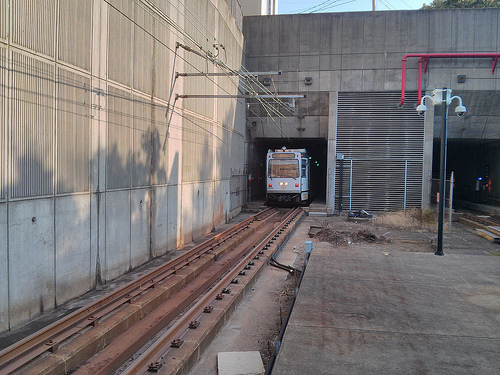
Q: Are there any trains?
A: Yes, there is a train.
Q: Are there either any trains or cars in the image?
A: Yes, there is a train.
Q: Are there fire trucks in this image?
A: No, there are no fire trucks.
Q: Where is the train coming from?
A: The train is coming from the tunnel.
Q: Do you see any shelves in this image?
A: No, there are no shelves.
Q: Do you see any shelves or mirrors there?
A: No, there are no shelves or mirrors.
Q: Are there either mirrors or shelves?
A: No, there are no shelves or mirrors.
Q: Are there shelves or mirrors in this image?
A: No, there are no shelves or mirrors.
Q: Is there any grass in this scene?
A: Yes, there is grass.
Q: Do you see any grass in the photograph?
A: Yes, there is grass.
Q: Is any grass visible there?
A: Yes, there is grass.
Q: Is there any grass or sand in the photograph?
A: Yes, there is grass.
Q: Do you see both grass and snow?
A: No, there is grass but no snow.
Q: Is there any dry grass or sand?
A: Yes, there is dry grass.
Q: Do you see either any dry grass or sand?
A: Yes, there is dry grass.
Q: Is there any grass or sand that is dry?
A: Yes, the grass is dry.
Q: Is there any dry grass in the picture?
A: Yes, there is dry grass.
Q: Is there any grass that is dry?
A: Yes, there is grass that is dry.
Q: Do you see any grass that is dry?
A: Yes, there is grass that is dry.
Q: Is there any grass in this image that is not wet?
A: Yes, there is dry grass.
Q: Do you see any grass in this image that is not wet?
A: Yes, there is dry grass.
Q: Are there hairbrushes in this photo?
A: No, there are no hairbrushes.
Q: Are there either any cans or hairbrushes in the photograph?
A: No, there are no hairbrushes or cans.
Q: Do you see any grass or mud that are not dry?
A: No, there is grass but it is dry.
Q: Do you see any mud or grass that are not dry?
A: No, there is grass but it is dry.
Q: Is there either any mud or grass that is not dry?
A: No, there is grass but it is dry.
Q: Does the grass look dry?
A: Yes, the grass is dry.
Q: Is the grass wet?
A: No, the grass is dry.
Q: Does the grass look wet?
A: No, the grass is dry.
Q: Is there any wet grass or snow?
A: No, there is grass but it is dry.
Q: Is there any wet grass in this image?
A: No, there is grass but it is dry.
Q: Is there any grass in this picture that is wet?
A: No, there is grass but it is dry.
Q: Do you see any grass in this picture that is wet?
A: No, there is grass but it is dry.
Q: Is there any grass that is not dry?
A: No, there is grass but it is dry.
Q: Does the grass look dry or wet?
A: The grass is dry.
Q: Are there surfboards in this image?
A: No, there are no surfboards.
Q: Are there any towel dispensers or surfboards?
A: No, there are no surfboards or towel dispensers.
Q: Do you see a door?
A: Yes, there is a door.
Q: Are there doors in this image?
A: Yes, there is a door.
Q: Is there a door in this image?
A: Yes, there is a door.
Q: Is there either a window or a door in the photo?
A: Yes, there is a door.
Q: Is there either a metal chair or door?
A: Yes, there is a metal door.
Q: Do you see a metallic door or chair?
A: Yes, there is a metal door.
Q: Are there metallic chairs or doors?
A: Yes, there is a metal door.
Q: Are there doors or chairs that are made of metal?
A: Yes, the door is made of metal.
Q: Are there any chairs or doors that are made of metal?
A: Yes, the door is made of metal.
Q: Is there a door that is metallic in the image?
A: Yes, there is a metal door.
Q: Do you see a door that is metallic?
A: Yes, there is a door that is metallic.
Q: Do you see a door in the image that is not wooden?
A: Yes, there is a metallic door.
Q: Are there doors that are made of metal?
A: Yes, there is a door that is made of metal.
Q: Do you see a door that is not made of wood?
A: Yes, there is a door that is made of metal.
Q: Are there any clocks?
A: No, there are no clocks.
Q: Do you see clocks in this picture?
A: No, there are no clocks.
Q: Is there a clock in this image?
A: No, there are no clocks.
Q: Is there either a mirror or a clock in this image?
A: No, there are no clocks or mirrors.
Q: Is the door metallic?
A: Yes, the door is metallic.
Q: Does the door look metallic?
A: Yes, the door is metallic.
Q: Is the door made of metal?
A: Yes, the door is made of metal.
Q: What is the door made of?
A: The door is made of metal.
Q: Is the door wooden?
A: No, the door is metallic.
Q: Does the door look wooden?
A: No, the door is metallic.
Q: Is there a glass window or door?
A: No, there is a door but it is metallic.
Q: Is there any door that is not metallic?
A: No, there is a door but it is metallic.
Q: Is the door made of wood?
A: No, the door is made of metal.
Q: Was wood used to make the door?
A: No, the door is made of metal.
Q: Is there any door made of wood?
A: No, there is a door but it is made of metal.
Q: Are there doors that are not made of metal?
A: No, there is a door but it is made of metal.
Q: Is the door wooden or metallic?
A: The door is metallic.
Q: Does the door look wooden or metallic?
A: The door is metallic.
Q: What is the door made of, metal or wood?
A: The door is made of metal.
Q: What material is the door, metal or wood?
A: The door is made of metal.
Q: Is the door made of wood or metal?
A: The door is made of metal.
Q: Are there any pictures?
A: No, there are no pictures.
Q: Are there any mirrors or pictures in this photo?
A: No, there are no pictures or mirrors.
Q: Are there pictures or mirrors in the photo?
A: No, there are no pictures or mirrors.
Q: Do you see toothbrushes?
A: No, there are no toothbrushes.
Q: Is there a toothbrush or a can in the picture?
A: No, there are no toothbrushes or cans.